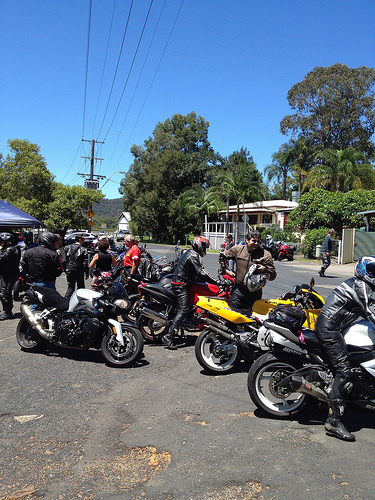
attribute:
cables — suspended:
[81, 23, 164, 93]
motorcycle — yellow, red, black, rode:
[20, 273, 145, 365]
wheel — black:
[103, 319, 156, 368]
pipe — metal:
[286, 372, 316, 398]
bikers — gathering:
[39, 225, 286, 327]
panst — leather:
[167, 286, 195, 344]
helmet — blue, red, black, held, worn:
[352, 254, 375, 286]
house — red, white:
[215, 197, 311, 239]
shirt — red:
[121, 245, 142, 270]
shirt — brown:
[232, 244, 285, 287]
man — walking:
[318, 227, 330, 279]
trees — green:
[265, 57, 370, 180]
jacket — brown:
[226, 249, 286, 302]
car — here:
[108, 225, 133, 245]